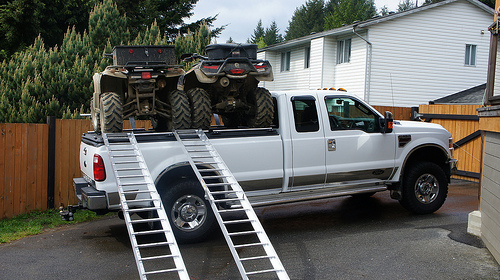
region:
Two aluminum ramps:
[95, 120, 292, 276]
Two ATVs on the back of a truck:
[81, 36, 276, 151]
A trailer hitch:
[49, 192, 82, 233]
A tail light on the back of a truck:
[91, 148, 111, 186]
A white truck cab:
[281, 77, 478, 226]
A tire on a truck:
[393, 143, 460, 224]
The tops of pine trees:
[2, 29, 92, 105]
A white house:
[274, 3, 477, 85]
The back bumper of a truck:
[64, 167, 116, 216]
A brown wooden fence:
[4, 105, 54, 220]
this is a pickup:
[273, 88, 431, 207]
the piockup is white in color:
[295, 141, 321, 171]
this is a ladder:
[107, 121, 174, 279]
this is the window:
[330, 98, 365, 123]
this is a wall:
[392, 23, 475, 105]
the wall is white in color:
[402, 42, 442, 85]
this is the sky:
[216, 6, 266, 22]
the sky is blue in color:
[234, 7, 257, 20]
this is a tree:
[33, 39, 65, 89]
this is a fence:
[11, 127, 47, 179]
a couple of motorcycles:
[62, 33, 282, 156]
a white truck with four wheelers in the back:
[72, 34, 464, 228]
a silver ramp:
[86, 118, 298, 278]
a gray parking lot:
[5, 160, 497, 277]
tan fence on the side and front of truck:
[5, 94, 499, 234]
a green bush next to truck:
[0, 0, 261, 131]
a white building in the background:
[237, 0, 497, 125]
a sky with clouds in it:
[140, 0, 417, 51]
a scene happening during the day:
[6, 4, 488, 278]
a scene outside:
[13, 11, 468, 272]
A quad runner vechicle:
[83, 39, 197, 135]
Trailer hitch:
[54, 197, 86, 227]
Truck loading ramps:
[103, 124, 289, 279]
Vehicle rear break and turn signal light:
[88, 152, 108, 184]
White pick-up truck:
[68, 85, 460, 242]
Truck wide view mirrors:
[376, 108, 397, 137]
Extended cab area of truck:
[285, 91, 334, 192]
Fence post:
[43, 112, 60, 214]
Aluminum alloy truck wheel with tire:
[398, 156, 456, 219]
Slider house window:
[458, 38, 481, 71]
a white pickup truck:
[63, 86, 466, 238]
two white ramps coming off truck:
[104, 131, 278, 278]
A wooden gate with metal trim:
[421, 99, 496, 207]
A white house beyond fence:
[243, 3, 499, 123]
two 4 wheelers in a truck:
[78, 9, 286, 145]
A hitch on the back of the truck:
[53, 198, 84, 225]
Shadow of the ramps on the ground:
[191, 233, 337, 279]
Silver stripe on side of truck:
[223, 171, 414, 196]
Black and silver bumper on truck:
[66, 170, 103, 220]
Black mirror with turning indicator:
[383, 107, 398, 147]